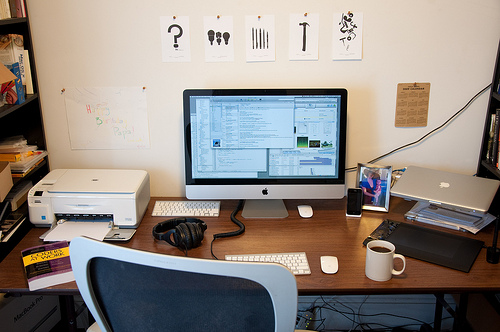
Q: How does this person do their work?
A: Online.